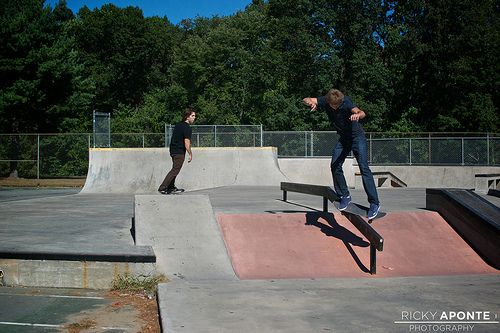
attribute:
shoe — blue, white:
[363, 200, 380, 224]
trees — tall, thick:
[142, 16, 473, 151]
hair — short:
[174, 102, 191, 121]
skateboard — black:
[332, 198, 384, 221]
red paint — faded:
[223, 212, 495, 276]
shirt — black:
[319, 104, 370, 159]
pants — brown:
[158, 152, 184, 189]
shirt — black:
[168, 122, 191, 155]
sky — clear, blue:
[42, 0, 395, 49]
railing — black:
[280, 182, 382, 273]